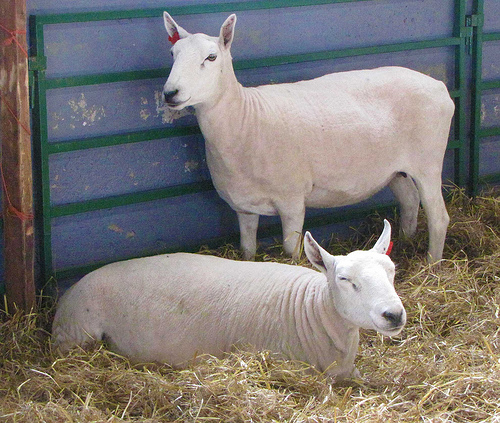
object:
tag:
[169, 33, 188, 46]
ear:
[158, 9, 188, 42]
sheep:
[51, 218, 413, 377]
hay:
[0, 183, 498, 421]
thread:
[2, 94, 38, 139]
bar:
[0, 5, 39, 326]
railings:
[26, 0, 496, 301]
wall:
[42, 0, 500, 278]